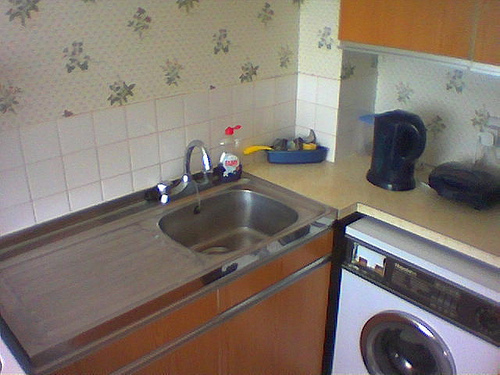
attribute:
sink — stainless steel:
[144, 145, 300, 254]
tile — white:
[4, 67, 401, 244]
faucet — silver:
[159, 137, 214, 198]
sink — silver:
[154, 179, 322, 268]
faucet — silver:
[166, 131, 221, 199]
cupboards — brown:
[334, 1, 496, 78]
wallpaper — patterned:
[0, 0, 296, 125]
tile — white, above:
[12, 102, 350, 187]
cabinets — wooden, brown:
[335, 2, 499, 69]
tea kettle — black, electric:
[364, 104, 431, 195]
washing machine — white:
[326, 225, 496, 372]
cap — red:
[220, 123, 243, 137]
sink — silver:
[152, 162, 301, 272]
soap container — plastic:
[215, 124, 245, 181]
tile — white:
[96, 149, 125, 169]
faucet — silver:
[163, 138, 223, 198]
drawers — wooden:
[37, 212, 346, 372]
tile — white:
[99, 137, 139, 177]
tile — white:
[156, 93, 186, 131]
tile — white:
[122, 102, 160, 144]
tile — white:
[90, 105, 128, 148]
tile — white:
[156, 153, 191, 182]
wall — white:
[2, 1, 301, 238]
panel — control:
[346, 245, 391, 285]